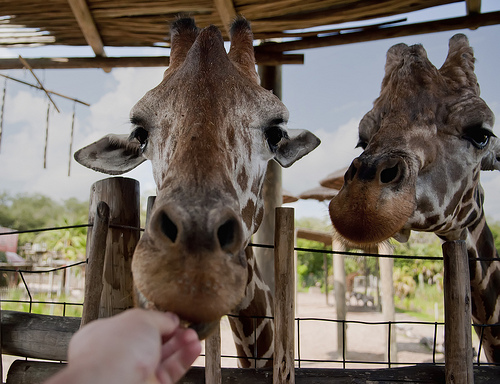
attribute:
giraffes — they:
[68, 13, 499, 380]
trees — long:
[4, 187, 497, 314]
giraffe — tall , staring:
[80, 17, 292, 382]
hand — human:
[47, 287, 211, 381]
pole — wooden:
[277, 205, 291, 382]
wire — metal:
[340, 316, 353, 371]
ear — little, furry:
[74, 133, 146, 174]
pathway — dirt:
[299, 291, 435, 361]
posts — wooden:
[62, 146, 475, 377]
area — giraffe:
[12, 52, 479, 365]